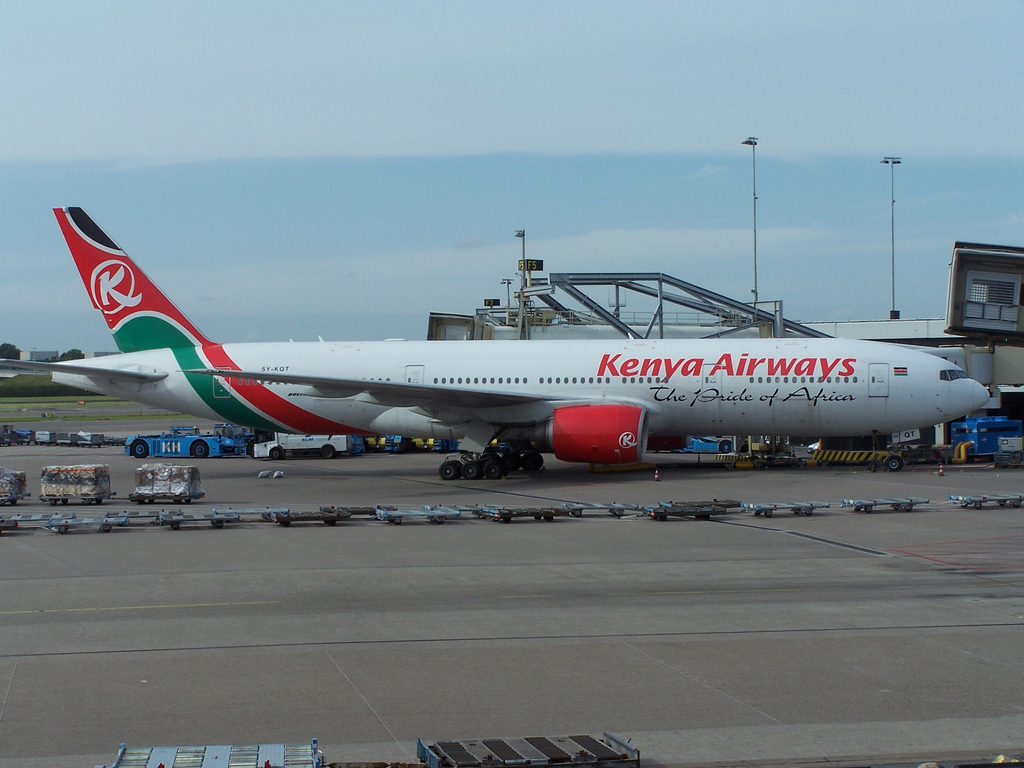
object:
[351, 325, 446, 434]
sidedoor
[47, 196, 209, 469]
tail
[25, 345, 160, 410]
wing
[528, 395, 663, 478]
engine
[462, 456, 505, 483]
wheel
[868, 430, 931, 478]
wheel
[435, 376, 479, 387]
window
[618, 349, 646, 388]
letter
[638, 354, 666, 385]
letter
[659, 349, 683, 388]
letter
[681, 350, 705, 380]
letter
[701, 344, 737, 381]
letter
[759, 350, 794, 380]
letter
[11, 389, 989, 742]
tarmac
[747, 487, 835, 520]
trailer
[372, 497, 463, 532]
trailer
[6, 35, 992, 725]
airport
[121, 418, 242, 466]
tractor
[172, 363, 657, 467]
wing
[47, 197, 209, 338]
tail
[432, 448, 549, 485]
tires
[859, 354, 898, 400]
door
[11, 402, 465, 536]
these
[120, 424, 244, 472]
cart